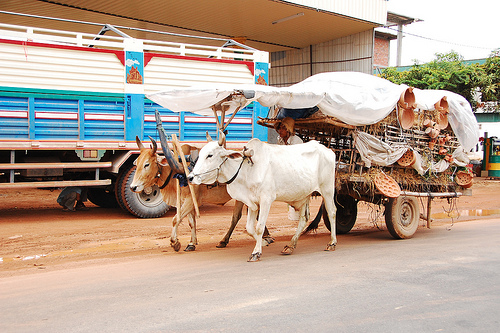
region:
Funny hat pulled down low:
[248, 111, 316, 153]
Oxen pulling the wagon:
[111, 119, 353, 273]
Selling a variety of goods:
[240, 66, 490, 225]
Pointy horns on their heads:
[120, 122, 244, 159]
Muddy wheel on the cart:
[353, 188, 441, 252]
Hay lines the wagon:
[333, 159, 479, 198]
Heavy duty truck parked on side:
[8, 6, 279, 233]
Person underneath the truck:
[51, 172, 105, 220]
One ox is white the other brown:
[119, 115, 366, 297]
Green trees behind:
[373, 38, 497, 116]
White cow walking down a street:
[191, 135, 370, 267]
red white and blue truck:
[0, 9, 295, 227]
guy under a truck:
[46, 149, 111, 240]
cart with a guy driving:
[265, 62, 492, 269]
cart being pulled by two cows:
[114, 61, 499, 313]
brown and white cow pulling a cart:
[109, 127, 434, 282]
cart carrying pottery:
[366, 79, 490, 253]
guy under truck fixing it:
[44, 163, 145, 229]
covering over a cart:
[143, 72, 435, 154]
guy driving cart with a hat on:
[257, 110, 323, 162]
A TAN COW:
[122, 140, 218, 259]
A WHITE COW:
[197, 137, 340, 267]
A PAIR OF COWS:
[133, 130, 334, 256]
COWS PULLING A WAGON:
[131, 85, 482, 260]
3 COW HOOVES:
[248, 244, 346, 264]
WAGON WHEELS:
[370, 195, 425, 235]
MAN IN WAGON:
[265, 120, 310, 165]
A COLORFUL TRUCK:
[3, 31, 268, 217]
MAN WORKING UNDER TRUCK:
[47, 165, 133, 211]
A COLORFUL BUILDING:
[473, 95, 499, 188]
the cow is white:
[268, 148, 285, 167]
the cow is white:
[263, 176, 285, 202]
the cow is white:
[252, 164, 272, 187]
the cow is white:
[273, 176, 288, 194]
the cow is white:
[258, 184, 268, 187]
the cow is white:
[272, 164, 283, 181]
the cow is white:
[260, 166, 276, 194]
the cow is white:
[263, 170, 280, 189]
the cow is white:
[276, 166, 289, 184]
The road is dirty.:
[134, 280, 496, 313]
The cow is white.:
[200, 137, 348, 239]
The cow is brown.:
[108, 117, 210, 256]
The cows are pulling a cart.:
[130, 69, 478, 281]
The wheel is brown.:
[353, 180, 433, 250]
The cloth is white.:
[207, 69, 492, 169]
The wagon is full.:
[153, 78, 495, 251]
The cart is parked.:
[3, 12, 281, 222]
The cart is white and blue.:
[7, 16, 284, 201]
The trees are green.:
[383, 47, 498, 100]